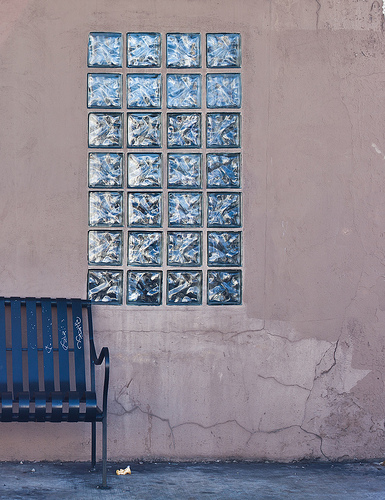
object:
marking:
[74, 316, 83, 349]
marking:
[58, 318, 69, 351]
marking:
[42, 306, 53, 354]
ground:
[6, 458, 384, 499]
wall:
[0, 0, 385, 466]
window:
[85, 31, 241, 307]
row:
[87, 31, 242, 69]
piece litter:
[115, 465, 131, 475]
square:
[165, 72, 202, 109]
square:
[127, 152, 164, 189]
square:
[167, 191, 202, 228]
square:
[87, 229, 123, 266]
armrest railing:
[87, 339, 110, 413]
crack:
[107, 330, 349, 464]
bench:
[0, 296, 112, 491]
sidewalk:
[0, 458, 385, 500]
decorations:
[86, 31, 243, 307]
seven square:
[205, 32, 242, 306]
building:
[0, 0, 385, 461]